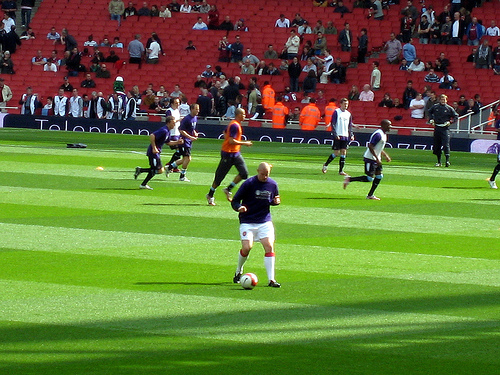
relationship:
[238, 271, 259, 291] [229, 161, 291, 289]
soccer ball near man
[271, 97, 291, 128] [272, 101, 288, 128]
man wearing coat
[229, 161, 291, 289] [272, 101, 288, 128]
man wearing coat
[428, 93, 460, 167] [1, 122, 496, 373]
man standing near field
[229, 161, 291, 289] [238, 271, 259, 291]
man near soccer ball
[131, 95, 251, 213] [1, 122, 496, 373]
men running across field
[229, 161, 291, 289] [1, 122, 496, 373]
man standing on field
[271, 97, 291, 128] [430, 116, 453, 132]
man holding h waist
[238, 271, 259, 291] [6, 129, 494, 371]
soccer ball on grass